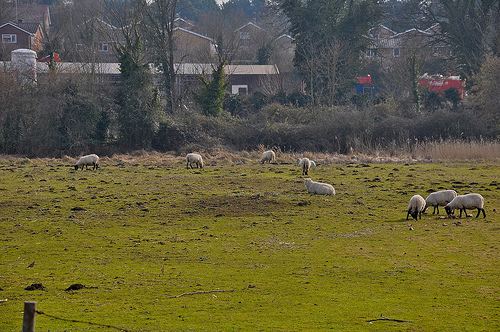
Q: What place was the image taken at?
A: It was taken at the field.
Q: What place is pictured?
A: It is a field.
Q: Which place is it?
A: It is a field.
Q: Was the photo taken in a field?
A: Yes, it was taken in a field.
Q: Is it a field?
A: Yes, it is a field.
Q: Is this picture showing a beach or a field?
A: It is showing a field.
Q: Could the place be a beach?
A: No, it is a field.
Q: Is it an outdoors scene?
A: Yes, it is outdoors.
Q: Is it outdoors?
A: Yes, it is outdoors.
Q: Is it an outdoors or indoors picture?
A: It is outdoors.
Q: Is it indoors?
A: No, it is outdoors.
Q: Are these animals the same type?
A: Yes, all the animals are sheep.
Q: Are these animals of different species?
A: No, all the animals are sheep.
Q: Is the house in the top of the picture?
A: Yes, the house is in the top of the image.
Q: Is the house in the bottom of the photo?
A: No, the house is in the top of the image.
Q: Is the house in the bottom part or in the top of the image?
A: The house is in the top of the image.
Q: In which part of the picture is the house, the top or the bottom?
A: The house is in the top of the image.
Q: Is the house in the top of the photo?
A: Yes, the house is in the top of the image.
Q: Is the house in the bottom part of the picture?
A: No, the house is in the top of the image.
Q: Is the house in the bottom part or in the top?
A: The house is in the top of the image.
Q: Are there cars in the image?
A: No, there are no cars.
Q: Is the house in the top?
A: Yes, the house is in the top of the image.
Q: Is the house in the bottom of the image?
A: No, the house is in the top of the image.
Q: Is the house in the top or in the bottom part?
A: The house is in the top of the image.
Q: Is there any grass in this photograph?
A: Yes, there is grass.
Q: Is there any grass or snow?
A: Yes, there is grass.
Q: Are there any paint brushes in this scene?
A: No, there are no paint brushes.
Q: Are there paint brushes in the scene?
A: No, there are no paint brushes.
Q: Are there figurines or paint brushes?
A: No, there are no paint brushes or figurines.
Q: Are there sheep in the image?
A: Yes, there is a sheep.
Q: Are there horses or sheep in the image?
A: Yes, there is a sheep.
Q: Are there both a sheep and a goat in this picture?
A: No, there is a sheep but no goats.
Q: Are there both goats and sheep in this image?
A: No, there is a sheep but no goats.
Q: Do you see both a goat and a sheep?
A: No, there is a sheep but no goats.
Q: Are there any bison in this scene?
A: No, there are no bison.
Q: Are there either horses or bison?
A: No, there are no bison or horses.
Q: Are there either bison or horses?
A: No, there are no bison or horses.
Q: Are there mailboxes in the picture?
A: No, there are no mailboxes.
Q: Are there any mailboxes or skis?
A: No, there are no mailboxes or skis.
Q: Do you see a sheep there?
A: Yes, there is a sheep.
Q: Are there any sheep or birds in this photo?
A: Yes, there is a sheep.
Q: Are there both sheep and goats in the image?
A: No, there is a sheep but no goats.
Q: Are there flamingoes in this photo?
A: No, there are no flamingoes.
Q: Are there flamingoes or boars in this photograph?
A: No, there are no flamingoes or boars.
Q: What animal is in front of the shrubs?
A: The sheep is in front of the shrubs.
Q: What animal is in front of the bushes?
A: The sheep is in front of the shrubs.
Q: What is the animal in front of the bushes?
A: The animal is a sheep.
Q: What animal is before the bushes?
A: The animal is a sheep.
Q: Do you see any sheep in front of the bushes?
A: Yes, there is a sheep in front of the bushes.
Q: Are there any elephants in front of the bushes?
A: No, there is a sheep in front of the bushes.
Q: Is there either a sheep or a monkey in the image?
A: Yes, there is a sheep.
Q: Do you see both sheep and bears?
A: No, there is a sheep but no bears.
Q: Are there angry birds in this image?
A: No, there are no angry birds.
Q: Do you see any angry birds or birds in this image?
A: No, there are no angry birds or birds.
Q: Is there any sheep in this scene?
A: Yes, there is a sheep.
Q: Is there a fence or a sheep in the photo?
A: Yes, there is a sheep.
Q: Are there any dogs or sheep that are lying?
A: Yes, the sheep is lying.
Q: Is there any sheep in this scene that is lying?
A: Yes, there is a sheep that is lying.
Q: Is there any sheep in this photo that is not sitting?
A: Yes, there is a sheep that is lying.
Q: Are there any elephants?
A: No, there are no elephants.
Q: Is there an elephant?
A: No, there are no elephants.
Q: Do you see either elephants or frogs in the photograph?
A: No, there are no elephants or frogs.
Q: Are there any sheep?
A: Yes, there is a sheep.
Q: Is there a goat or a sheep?
A: Yes, there is a sheep.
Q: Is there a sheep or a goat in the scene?
A: Yes, there is a sheep.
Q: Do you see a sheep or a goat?
A: Yes, there is a sheep.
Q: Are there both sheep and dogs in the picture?
A: No, there is a sheep but no dogs.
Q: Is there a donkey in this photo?
A: No, there are no donkeys.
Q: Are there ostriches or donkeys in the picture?
A: No, there are no donkeys or ostriches.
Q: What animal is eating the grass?
A: The sheep is eating the grass.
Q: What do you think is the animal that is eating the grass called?
A: The animal is a sheep.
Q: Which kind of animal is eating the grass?
A: The animal is a sheep.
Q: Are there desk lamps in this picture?
A: No, there are no desk lamps.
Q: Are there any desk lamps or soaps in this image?
A: No, there are no desk lamps or soaps.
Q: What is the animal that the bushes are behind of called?
A: The animal is a sheep.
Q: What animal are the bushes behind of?
A: The bushes are behind the sheep.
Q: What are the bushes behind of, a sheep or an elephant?
A: The bushes are behind a sheep.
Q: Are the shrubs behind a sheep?
A: Yes, the shrubs are behind a sheep.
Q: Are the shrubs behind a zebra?
A: No, the shrubs are behind a sheep.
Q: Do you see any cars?
A: No, there are no cars.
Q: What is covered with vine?
A: The tree is covered with vine.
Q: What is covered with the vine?
A: The tree is covered with vine.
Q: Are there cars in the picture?
A: No, there are no cars.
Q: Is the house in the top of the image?
A: Yes, the house is in the top of the image.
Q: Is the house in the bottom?
A: No, the house is in the top of the image.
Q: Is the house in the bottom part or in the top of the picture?
A: The house is in the top of the image.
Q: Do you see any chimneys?
A: No, there are no chimneys.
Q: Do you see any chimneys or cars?
A: No, there are no chimneys or cars.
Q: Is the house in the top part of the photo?
A: Yes, the house is in the top of the image.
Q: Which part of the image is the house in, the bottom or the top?
A: The house is in the top of the image.